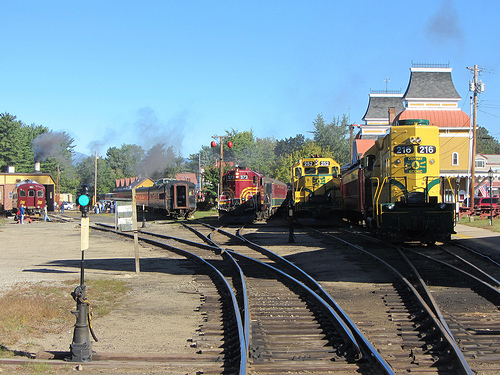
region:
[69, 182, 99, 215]
Green Light on pole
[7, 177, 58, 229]
Red Railroad car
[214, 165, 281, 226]
Red and yellow train engine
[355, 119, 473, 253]
Number 216 Train engine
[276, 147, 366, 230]
Red and green Train engine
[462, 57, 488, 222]
Power line pole with breakers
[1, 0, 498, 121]
Blue cloudless skies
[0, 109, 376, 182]
Green trees in the distance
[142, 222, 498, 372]
Steel rail road tracks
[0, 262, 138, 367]
Patch of green and brown grass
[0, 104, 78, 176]
a tall tree with green leaves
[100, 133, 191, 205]
a tall tree with green leaves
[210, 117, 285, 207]
a tall tree with green leaves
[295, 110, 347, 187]
a tall tree with green leaves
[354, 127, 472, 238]
a yellow train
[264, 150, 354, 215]
a yellow train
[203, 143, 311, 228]
a red train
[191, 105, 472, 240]
three trains side by side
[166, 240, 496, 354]
three rows of train tracks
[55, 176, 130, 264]
a green light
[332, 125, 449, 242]
train on the train tracks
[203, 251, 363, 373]
train tracks on the ground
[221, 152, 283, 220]
red train on the tracks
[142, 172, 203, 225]
brown train on the tracks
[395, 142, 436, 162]
numbers on the train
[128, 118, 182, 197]
smoke in the air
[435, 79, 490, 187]
building in the background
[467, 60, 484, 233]
utility pole next to the building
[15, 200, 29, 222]
person in front of a train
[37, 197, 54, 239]
person in front of a train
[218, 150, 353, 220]
red and yellow train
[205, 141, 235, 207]
the red train speakers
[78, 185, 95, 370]
turquoise light on post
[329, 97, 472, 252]
yelow and green train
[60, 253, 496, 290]
yellow and green train shadow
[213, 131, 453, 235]
three trains in a row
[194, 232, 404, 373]
black train tracks for trains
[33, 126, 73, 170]
gray smoke coming out of house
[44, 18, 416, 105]
blue sky on a sunny day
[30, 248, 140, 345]
dried grass on feild of trains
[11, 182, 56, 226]
A red train with two people standing in front of it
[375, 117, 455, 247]
A yellow and green train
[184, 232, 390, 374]
metal and wood train tracks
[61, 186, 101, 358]
An old fashoned train sign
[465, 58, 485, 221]
A large telephone pole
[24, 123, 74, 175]
Train smoke rising into the sky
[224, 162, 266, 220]
A red and yellow train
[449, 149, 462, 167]
A small white window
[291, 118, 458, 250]
Two large yellow trains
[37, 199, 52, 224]
A person in a white shirt